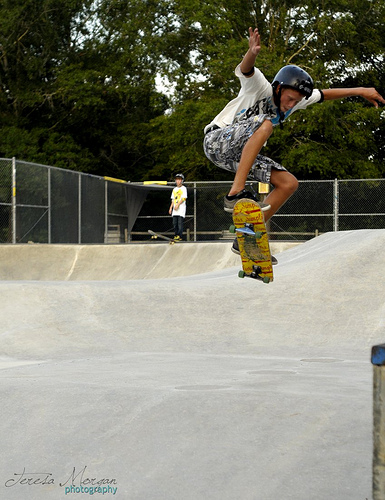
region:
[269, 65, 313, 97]
shiny black helmet for safety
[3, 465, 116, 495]
name of the photographer responsible for this work of art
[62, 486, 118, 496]
photography typed in calibri font and colored bluish green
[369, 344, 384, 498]
very edge of the stair rail obstacle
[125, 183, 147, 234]
area of chainlink fence that was cut and moved over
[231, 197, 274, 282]
bottom of a skateboard that has red script lettering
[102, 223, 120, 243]
plastic garbage can with lid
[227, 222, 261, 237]
silver truks with greenish wheels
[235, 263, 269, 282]
black truks with greenish wheels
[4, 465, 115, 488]
black script writing made with a pen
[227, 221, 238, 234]
wheel of the skateboard.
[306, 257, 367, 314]
concrete ramp in skate park.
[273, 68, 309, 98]
helmet on skater's head.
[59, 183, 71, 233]
fence near the ramp.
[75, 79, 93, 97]
leaves on the tree.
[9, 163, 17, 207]
post of the fence.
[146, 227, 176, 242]
skateboard near the skater.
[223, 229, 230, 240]
bench made of wood.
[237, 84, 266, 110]
shirt on the skater.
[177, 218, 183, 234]
jeans on the skater.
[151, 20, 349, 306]
a boy that is skateboarding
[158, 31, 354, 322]
a boy on a skateboard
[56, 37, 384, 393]
a boy at a skatepark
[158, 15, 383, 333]
a boy on a yellow skateboard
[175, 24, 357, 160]
a boy wearing a helmet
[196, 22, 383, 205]
a boy wearing black helmet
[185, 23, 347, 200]
a boy wearing a shirt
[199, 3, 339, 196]
a boy wearing a white shirt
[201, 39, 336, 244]
a boy wearing shorts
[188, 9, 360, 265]
a skateboarder wearing a helmet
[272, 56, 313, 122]
THE BOY IS WEARING A HELMET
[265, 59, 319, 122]
THE BOY'S HELMET IS BLACK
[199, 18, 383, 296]
THE BOY IS DOING A TRICK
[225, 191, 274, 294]
THE BOY HAS A SKATEBOARD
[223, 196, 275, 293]
THE SKATEBOARD IS YELLOW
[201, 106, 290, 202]
THE BOY IS WEARING SHORTS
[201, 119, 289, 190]
THE BOY'S SHORTS ARE BLACK AND WHITE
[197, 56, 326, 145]
THE BOY IS WEARING A T-SHIRT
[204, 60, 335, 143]
THE BOY'S T-SHIRT IS BLACK AND WHITE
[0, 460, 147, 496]
THE PHOTOGRAPHER'S NAME IS AT THE BOTTOM LEFT CORNER OF THE PICTURE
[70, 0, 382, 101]
patches of blue sky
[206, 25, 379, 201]
boy with oustretched arms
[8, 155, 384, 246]
chain link fence on poles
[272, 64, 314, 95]
black helmet on head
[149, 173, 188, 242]
boy standing on skateboard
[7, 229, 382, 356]
ramps in skate park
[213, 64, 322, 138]
short sleeve white shirt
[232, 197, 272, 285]
four wheels under skateboard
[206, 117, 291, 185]
shorts on boy's legs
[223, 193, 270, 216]
sneaker with white sole